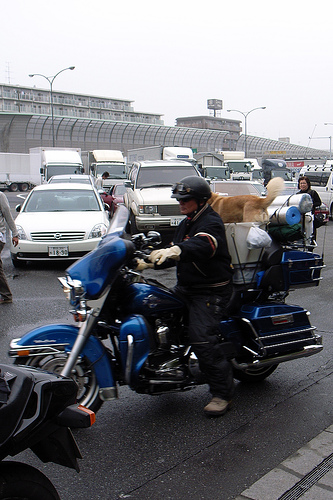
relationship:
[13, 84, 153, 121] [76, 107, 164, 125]
building with balconies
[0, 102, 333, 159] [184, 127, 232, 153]
stadium wall like stadium wall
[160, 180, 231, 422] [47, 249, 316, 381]
man on motorcycle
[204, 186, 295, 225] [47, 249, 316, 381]
dog on motorcycle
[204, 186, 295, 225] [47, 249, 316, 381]
dog standing on motorcycle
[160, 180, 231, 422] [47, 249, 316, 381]
man driving motorcycle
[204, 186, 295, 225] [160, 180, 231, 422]
dog behind man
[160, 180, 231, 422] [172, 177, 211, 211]
man wears helmet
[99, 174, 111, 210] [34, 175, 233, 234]
person walking by cars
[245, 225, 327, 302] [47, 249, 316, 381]
items strapped on motorcycle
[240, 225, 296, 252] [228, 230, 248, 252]
bag hanging from container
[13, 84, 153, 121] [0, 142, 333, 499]
building behind in parking lot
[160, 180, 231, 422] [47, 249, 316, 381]
man sitting on motorcycle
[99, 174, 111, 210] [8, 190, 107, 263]
person entering car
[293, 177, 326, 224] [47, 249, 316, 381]
woman looking at motorcycle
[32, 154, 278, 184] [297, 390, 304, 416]
tractor trailors parked in parking lot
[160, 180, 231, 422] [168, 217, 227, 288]
man in jacket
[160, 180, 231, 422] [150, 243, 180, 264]
man wears gloves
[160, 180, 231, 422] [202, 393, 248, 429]
man wears shoes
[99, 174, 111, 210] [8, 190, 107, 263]
person getting in car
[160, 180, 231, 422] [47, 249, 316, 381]
man riding motorcycle